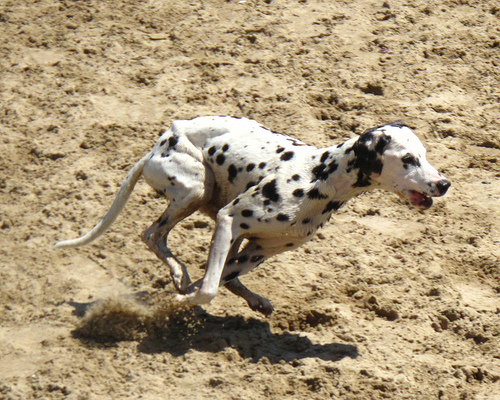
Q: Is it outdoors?
A: Yes, it is outdoors.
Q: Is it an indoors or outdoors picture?
A: It is outdoors.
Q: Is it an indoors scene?
A: No, it is outdoors.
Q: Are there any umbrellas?
A: No, there are no umbrellas.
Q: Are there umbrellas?
A: No, there are no umbrellas.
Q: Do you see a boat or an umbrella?
A: No, there are no umbrellas or boats.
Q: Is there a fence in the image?
A: No, there are no fences.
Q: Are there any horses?
A: No, there are no horses.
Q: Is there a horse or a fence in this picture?
A: No, there are no horses or fences.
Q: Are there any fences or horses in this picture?
A: No, there are no horses or fences.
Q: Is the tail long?
A: Yes, the tail is long.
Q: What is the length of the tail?
A: The tail is long.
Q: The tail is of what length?
A: The tail is long.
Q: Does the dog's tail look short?
A: No, the tail is long.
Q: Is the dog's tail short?
A: No, the tail is long.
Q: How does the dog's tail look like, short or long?
A: The tail is long.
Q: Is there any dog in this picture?
A: Yes, there is a dog.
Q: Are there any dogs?
A: Yes, there is a dog.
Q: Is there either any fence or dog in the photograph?
A: Yes, there is a dog.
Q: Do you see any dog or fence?
A: Yes, there is a dog.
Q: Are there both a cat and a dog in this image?
A: No, there is a dog but no cats.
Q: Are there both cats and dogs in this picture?
A: No, there is a dog but no cats.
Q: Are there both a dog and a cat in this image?
A: No, there is a dog but no cats.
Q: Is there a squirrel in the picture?
A: No, there are no squirrels.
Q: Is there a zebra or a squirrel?
A: No, there are no squirrels or zebras.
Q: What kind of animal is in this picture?
A: The animal is a dog.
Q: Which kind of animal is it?
A: The animal is a dog.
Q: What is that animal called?
A: This is a dog.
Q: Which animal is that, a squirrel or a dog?
A: This is a dog.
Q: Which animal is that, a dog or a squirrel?
A: This is a dog.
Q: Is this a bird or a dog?
A: This is a dog.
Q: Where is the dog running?
A: The dog is running on the beach.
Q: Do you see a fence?
A: No, there are no fences.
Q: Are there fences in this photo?
A: No, there are no fences.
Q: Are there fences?
A: No, there are no fences.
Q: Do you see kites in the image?
A: No, there are no kites.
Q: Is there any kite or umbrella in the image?
A: No, there are no kites or umbrellas.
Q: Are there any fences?
A: No, there are no fences.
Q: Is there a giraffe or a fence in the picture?
A: No, there are no fences or giraffes.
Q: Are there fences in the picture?
A: No, there are no fences.